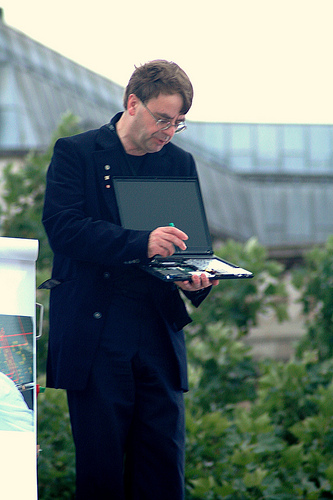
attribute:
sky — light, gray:
[4, 5, 332, 128]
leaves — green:
[243, 238, 268, 274]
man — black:
[28, 51, 227, 498]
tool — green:
[164, 218, 189, 258]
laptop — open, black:
[110, 175, 255, 283]